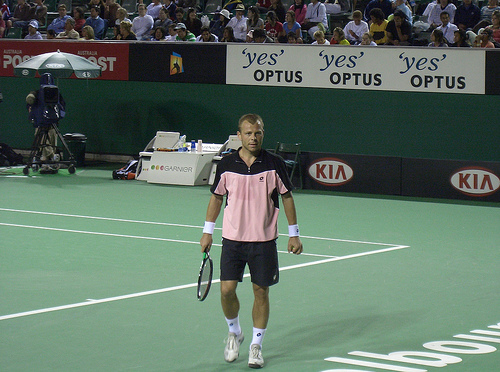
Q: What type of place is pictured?
A: It is a field.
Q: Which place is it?
A: It is a field.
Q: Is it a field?
A: Yes, it is a field.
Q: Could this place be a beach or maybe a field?
A: It is a field.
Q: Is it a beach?
A: No, it is a field.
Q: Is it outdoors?
A: Yes, it is outdoors.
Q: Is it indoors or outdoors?
A: It is outdoors.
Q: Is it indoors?
A: No, it is outdoors.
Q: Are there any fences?
A: No, there are no fences.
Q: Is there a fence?
A: No, there are no fences.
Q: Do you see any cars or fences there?
A: No, there are no fences or cars.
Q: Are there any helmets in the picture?
A: No, there are no helmets.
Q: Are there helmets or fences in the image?
A: No, there are no helmets or fences.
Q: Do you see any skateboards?
A: No, there are no skateboards.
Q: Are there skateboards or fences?
A: No, there are no skateboards or fences.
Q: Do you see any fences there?
A: No, there are no fences.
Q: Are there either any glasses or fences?
A: No, there are no fences or glasses.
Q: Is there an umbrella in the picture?
A: Yes, there is an umbrella.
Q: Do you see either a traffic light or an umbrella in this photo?
A: Yes, there is an umbrella.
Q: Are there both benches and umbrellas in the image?
A: No, there is an umbrella but no benches.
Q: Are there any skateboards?
A: No, there are no skateboards.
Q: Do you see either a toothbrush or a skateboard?
A: No, there are no skateboards or toothbrushes.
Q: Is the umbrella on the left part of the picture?
A: Yes, the umbrella is on the left of the image.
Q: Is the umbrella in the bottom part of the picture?
A: No, the umbrella is in the top of the image.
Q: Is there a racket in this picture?
A: Yes, there is a racket.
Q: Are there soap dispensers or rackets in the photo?
A: Yes, there is a racket.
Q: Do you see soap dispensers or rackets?
A: Yes, there is a racket.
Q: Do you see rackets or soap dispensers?
A: Yes, there is a racket.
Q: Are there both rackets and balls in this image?
A: No, there is a racket but no balls.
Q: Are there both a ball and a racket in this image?
A: No, there is a racket but no balls.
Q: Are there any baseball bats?
A: No, there are no baseball bats.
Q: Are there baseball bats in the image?
A: No, there are no baseball bats.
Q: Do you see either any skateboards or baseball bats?
A: No, there are no baseball bats or skateboards.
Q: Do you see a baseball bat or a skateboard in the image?
A: No, there are no baseball bats or skateboards.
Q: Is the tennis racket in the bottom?
A: Yes, the tennis racket is in the bottom of the image.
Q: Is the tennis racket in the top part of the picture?
A: No, the tennis racket is in the bottom of the image.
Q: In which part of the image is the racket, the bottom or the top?
A: The racket is in the bottom of the image.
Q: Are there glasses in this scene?
A: No, there are no glasses.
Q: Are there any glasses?
A: No, there are no glasses.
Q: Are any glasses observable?
A: No, there are no glasses.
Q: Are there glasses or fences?
A: No, there are no glasses or fences.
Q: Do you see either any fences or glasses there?
A: No, there are no glasses or fences.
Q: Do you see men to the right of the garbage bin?
A: Yes, there is a man to the right of the garbage bin.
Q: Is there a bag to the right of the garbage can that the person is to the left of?
A: No, there is a man to the right of the trashcan.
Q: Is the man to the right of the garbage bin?
A: Yes, the man is to the right of the garbage bin.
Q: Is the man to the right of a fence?
A: No, the man is to the right of the garbage bin.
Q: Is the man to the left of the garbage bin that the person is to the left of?
A: No, the man is to the right of the garbage bin.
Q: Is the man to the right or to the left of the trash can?
A: The man is to the right of the trash can.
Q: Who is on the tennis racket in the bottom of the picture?
A: The man is on the racket.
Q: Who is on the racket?
A: The man is on the racket.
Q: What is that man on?
A: The man is on the tennis racket.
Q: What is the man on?
A: The man is on the tennis racket.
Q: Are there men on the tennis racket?
A: Yes, there is a man on the tennis racket.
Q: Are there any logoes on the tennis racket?
A: No, there is a man on the tennis racket.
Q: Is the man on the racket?
A: Yes, the man is on the racket.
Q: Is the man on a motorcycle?
A: No, the man is on the racket.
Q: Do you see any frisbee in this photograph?
A: No, there are no frisbees.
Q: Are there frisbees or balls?
A: No, there are no frisbees or balls.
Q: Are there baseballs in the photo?
A: No, there are no baseballs.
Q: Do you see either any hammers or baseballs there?
A: No, there are no baseballs or hammers.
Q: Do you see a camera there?
A: Yes, there is a camera.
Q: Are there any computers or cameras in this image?
A: Yes, there is a camera.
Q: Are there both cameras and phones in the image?
A: No, there is a camera but no phones.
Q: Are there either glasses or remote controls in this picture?
A: No, there are no glasses or remote controls.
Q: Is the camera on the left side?
A: Yes, the camera is on the left of the image.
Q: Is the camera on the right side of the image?
A: No, the camera is on the left of the image.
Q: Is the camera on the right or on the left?
A: The camera is on the left of the image.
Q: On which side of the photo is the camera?
A: The camera is on the left of the image.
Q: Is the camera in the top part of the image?
A: Yes, the camera is in the top of the image.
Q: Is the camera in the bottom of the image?
A: No, the camera is in the top of the image.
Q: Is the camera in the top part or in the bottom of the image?
A: The camera is in the top of the image.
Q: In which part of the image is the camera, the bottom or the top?
A: The camera is in the top of the image.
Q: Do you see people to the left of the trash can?
A: Yes, there is a person to the left of the trash can.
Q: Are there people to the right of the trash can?
A: No, the person is to the left of the trash can.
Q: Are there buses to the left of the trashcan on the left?
A: No, there is a person to the left of the trash can.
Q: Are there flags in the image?
A: No, there are no flags.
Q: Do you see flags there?
A: No, there are no flags.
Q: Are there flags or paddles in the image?
A: No, there are no flags or paddles.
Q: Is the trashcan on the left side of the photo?
A: Yes, the trashcan is on the left of the image.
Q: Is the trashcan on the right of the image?
A: No, the trashcan is on the left of the image.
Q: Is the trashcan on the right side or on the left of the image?
A: The trashcan is on the left of the image.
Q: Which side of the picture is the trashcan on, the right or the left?
A: The trashcan is on the left of the image.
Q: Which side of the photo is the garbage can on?
A: The garbage can is on the left of the image.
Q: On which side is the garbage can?
A: The garbage can is on the left of the image.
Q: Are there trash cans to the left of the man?
A: Yes, there is a trash can to the left of the man.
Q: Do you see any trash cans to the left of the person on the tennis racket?
A: Yes, there is a trash can to the left of the man.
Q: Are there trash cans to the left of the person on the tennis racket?
A: Yes, there is a trash can to the left of the man.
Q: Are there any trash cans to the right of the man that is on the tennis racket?
A: No, the trash can is to the left of the man.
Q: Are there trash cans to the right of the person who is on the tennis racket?
A: No, the trash can is to the left of the man.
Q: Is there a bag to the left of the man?
A: No, there is a trash can to the left of the man.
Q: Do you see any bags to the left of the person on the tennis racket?
A: No, there is a trash can to the left of the man.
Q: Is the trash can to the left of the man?
A: Yes, the trash can is to the left of the man.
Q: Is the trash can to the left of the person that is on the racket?
A: Yes, the trash can is to the left of the man.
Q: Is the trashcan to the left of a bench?
A: No, the trashcan is to the left of the man.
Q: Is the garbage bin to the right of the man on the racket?
A: No, the garbage bin is to the left of the man.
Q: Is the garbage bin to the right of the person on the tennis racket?
A: No, the garbage bin is to the left of the man.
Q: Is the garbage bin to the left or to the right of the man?
A: The garbage bin is to the left of the man.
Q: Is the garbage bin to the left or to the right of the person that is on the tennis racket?
A: The garbage bin is to the left of the man.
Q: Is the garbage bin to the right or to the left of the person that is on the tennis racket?
A: The garbage bin is to the left of the man.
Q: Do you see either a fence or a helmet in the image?
A: No, there are no fences or helmets.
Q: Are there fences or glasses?
A: No, there are no glasses or fences.